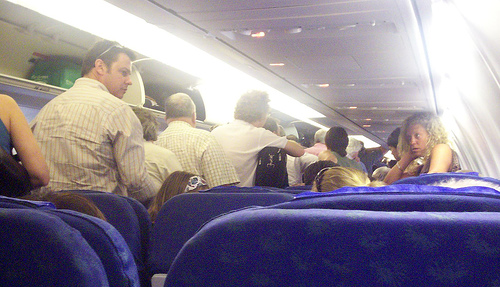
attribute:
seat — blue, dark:
[169, 186, 274, 246]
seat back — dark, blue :
[166, 209, 497, 285]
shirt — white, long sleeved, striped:
[27, 76, 159, 191]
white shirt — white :
[209, 118, 289, 191]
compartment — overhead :
[8, 13, 53, 95]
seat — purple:
[162, 200, 497, 285]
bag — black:
[252, 137, 297, 190]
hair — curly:
[397, 108, 445, 171]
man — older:
[153, 88, 239, 190]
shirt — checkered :
[153, 121, 238, 191]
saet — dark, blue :
[36, 187, 161, 267]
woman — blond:
[380, 104, 470, 188]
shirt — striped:
[30, 81, 164, 197]